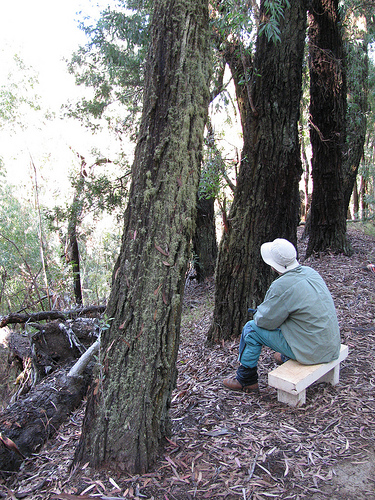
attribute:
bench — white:
[267, 341, 352, 411]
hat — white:
[261, 238, 302, 273]